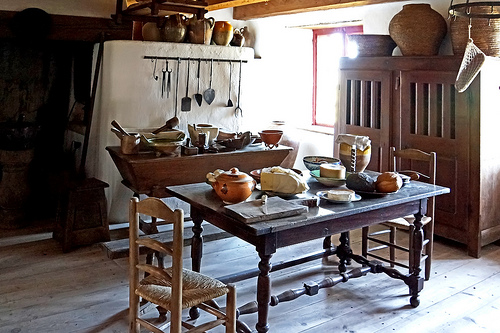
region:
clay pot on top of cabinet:
[387, 2, 446, 55]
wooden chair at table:
[127, 193, 239, 331]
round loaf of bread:
[377, 170, 403, 190]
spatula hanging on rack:
[182, 60, 192, 109]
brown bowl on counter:
[257, 128, 282, 146]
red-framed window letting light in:
[310, 23, 365, 131]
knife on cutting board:
[260, 193, 270, 215]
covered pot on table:
[205, 166, 256, 203]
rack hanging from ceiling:
[443, 0, 498, 27]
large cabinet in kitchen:
[337, 57, 498, 258]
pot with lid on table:
[198, 156, 255, 203]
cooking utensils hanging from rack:
[145, 48, 256, 115]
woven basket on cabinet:
[392, 5, 441, 50]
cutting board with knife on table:
[230, 188, 292, 218]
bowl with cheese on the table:
[308, 154, 344, 181]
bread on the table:
[347, 163, 402, 190]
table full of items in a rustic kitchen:
[162, 159, 463, 309]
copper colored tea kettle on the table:
[208, 165, 255, 204]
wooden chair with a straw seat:
[115, 196, 245, 331]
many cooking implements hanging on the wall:
[144, 49, 256, 124]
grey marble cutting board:
[226, 199, 313, 224]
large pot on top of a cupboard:
[386, 2, 450, 59]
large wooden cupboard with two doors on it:
[334, 59, 493, 239]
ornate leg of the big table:
[408, 194, 430, 307]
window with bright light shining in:
[292, 26, 357, 134]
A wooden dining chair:
[126, 193, 238, 331]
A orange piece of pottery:
[213, 167, 259, 207]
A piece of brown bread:
[373, 170, 404, 194]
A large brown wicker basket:
[388, 2, 449, 57]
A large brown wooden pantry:
[333, 53, 499, 260]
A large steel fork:
[233, 58, 243, 119]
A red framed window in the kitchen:
[309, 24, 366, 128]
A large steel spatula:
[178, 57, 192, 114]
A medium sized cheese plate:
[315, 187, 362, 204]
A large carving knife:
[257, 192, 270, 216]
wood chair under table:
[125, 193, 237, 332]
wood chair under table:
[373, 148, 431, 280]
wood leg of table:
[250, 256, 270, 331]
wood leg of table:
[188, 205, 205, 318]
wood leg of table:
[410, 219, 420, 304]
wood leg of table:
[339, 237, 346, 262]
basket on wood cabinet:
[352, 28, 392, 55]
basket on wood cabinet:
[384, 2, 449, 55]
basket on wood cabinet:
[448, 6, 493, 56]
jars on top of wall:
[132, 13, 256, 45]